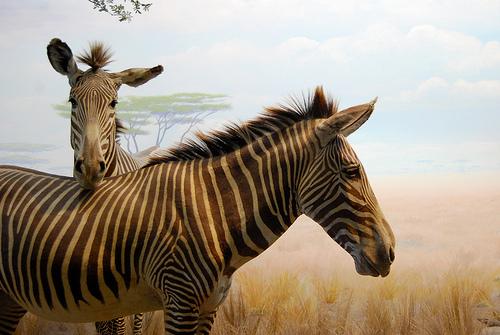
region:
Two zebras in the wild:
[3, 31, 404, 334]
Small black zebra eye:
[332, 158, 367, 189]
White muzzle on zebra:
[337, 216, 427, 284]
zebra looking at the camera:
[32, 36, 169, 188]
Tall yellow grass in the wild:
[220, 248, 497, 333]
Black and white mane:
[145, 87, 333, 181]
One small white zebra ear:
[42, 34, 87, 79]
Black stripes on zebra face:
[305, 115, 385, 290]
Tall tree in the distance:
[38, 70, 240, 177]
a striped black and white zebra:
[1, 95, 393, 333]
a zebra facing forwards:
[46, 40, 156, 187]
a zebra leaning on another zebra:
[20, 38, 410, 334]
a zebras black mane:
[151, 93, 334, 167]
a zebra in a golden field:
[178, 85, 499, 332]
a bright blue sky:
[145, 0, 490, 88]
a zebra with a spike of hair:
[41, 38, 160, 183]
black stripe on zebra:
[229, 153, 259, 203]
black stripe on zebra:
[155, 162, 166, 204]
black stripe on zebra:
[126, 168, 140, 184]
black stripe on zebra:
[263, 134, 280, 161]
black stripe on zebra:
[13, 167, 28, 192]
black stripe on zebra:
[10, 232, 42, 263]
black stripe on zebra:
[50, 263, 72, 298]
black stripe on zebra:
[79, 267, 110, 290]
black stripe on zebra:
[113, 249, 144, 269]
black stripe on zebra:
[155, 237, 175, 270]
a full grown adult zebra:
[0, 125, 498, 333]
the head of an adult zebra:
[274, 66, 426, 283]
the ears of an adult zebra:
[315, 101, 380, 141]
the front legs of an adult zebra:
[140, 293, 214, 333]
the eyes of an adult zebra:
[322, 136, 374, 190]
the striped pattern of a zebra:
[21, 218, 138, 282]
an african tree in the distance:
[161, 83, 228, 138]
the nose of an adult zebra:
[77, 143, 112, 195]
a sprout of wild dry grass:
[424, 255, 475, 333]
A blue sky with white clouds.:
[1, 2, 499, 173]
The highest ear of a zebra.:
[46, 38, 79, 77]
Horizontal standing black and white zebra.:
[0, 88, 397, 334]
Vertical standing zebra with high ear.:
[46, 38, 163, 334]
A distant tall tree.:
[53, 91, 233, 153]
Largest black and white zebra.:
[1, 86, 394, 334]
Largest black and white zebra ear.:
[44, 36, 76, 81]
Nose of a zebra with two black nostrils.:
[73, 159, 105, 186]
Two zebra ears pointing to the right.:
[316, 96, 379, 143]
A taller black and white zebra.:
[46, 36, 166, 333]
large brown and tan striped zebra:
[1, 84, 402, 334]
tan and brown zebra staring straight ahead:
[45, 34, 165, 186]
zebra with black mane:
[1, 87, 406, 333]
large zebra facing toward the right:
[2, 85, 397, 334]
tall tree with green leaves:
[49, 90, 233, 154]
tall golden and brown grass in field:
[0, 266, 498, 334]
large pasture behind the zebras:
[228, 176, 499, 278]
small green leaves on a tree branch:
[85, 1, 153, 23]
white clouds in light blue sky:
[183, 21, 495, 112]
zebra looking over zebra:
[44, 37, 174, 187]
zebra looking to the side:
[1, 85, 395, 334]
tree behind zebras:
[55, 91, 232, 153]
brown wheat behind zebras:
[13, 174, 498, 334]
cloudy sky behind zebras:
[0, 0, 497, 174]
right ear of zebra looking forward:
[46, 37, 81, 79]